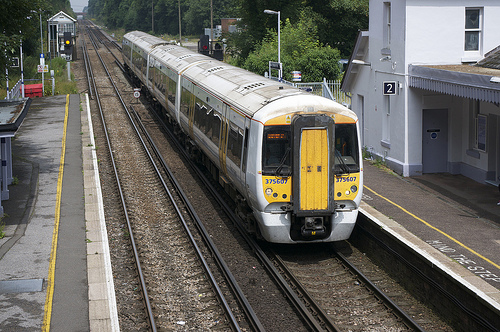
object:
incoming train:
[118, 29, 364, 245]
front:
[255, 104, 363, 244]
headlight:
[346, 190, 351, 195]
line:
[44, 93, 71, 331]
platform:
[360, 163, 499, 310]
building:
[340, 0, 499, 191]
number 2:
[387, 84, 393, 93]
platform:
[0, 93, 88, 331]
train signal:
[64, 32, 73, 55]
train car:
[177, 59, 364, 244]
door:
[299, 128, 328, 210]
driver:
[335, 149, 342, 157]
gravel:
[173, 176, 303, 332]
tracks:
[81, 60, 256, 331]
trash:
[177, 321, 186, 326]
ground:
[0, 92, 120, 331]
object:
[20, 83, 43, 98]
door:
[422, 109, 449, 174]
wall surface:
[409, 6, 460, 64]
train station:
[0, 27, 500, 332]